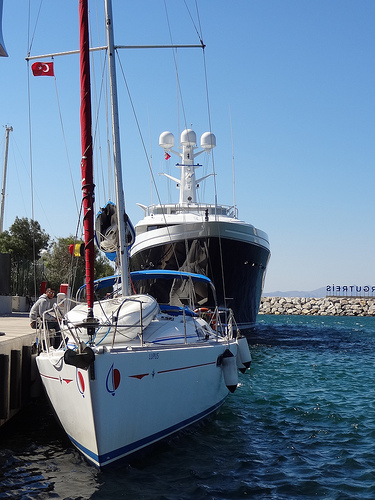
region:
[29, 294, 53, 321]
the man is wearing a hoodie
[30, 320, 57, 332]
the man is wearing long pants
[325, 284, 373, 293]
a sign is in the background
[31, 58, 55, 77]
a flag is on a cable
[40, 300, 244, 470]
the boat is painted white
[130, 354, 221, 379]
a line is across the boat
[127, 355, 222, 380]
the line is red in color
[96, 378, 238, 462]
a line runs across the bottom of the boat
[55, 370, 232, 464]
the line is blue in color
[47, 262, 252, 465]
the boat is on the water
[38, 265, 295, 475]
a small white boat on the water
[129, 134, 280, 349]
a large black and white yacht on the water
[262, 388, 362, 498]
choppy blue waters of the ocean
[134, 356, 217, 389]
red stripe on the white boat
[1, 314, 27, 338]
grey concrete surface of the loading dock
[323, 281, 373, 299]
black letters on posts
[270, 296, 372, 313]
rock wall of the dam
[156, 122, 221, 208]
white radio antennas of the boat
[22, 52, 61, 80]
a red flag waving in the wind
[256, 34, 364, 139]
clear blue skies over the scene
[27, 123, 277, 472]
These are boats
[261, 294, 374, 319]
That is a rocky shore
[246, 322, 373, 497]
That is the cruel unforgiving sea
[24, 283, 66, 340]
That is a person enjoying a boat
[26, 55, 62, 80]
That is a national flag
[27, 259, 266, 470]
That is a white boat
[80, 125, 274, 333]
that is a large black boat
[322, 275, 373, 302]
That is a sign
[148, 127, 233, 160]
Those are radar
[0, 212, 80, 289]
Those are trees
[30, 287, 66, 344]
A man sitting on the edge of a pier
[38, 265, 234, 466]
A small white and blue boat in the water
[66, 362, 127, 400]
Designs on the front of boat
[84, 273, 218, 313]
The front window of a boat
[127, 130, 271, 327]
A larger boat behind the small one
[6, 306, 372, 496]
A body of water with small waves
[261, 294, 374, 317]
A rock wall in the water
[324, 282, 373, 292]
Supported letters by the water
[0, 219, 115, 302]
Trees by the water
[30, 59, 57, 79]
A flag on the mast of a boat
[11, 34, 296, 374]
This is in a harbor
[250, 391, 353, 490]
this is a body of water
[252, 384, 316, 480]
the water is turqoise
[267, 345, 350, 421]
the water is green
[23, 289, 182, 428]
this is a boat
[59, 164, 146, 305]
this is a pole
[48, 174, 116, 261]
the pole is red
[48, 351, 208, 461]
the boat is white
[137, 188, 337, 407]
this boat is large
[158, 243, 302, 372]
the bottom of the boat is black